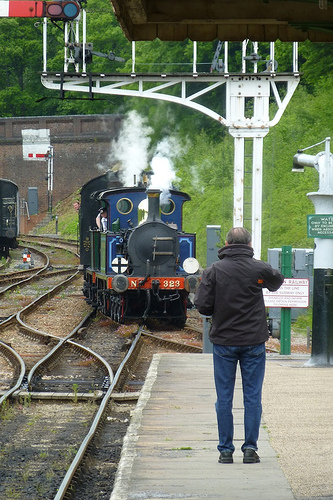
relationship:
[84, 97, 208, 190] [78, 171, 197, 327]
steam on top of train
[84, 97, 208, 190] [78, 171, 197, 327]
steam coming from train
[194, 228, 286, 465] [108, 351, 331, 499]
man on platform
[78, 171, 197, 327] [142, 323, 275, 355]
train on tracks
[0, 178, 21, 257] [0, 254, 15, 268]
train on tracks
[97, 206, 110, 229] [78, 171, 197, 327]
conductor on train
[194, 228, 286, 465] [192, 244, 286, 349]
man wearing a jacket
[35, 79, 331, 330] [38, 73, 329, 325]
hill has grass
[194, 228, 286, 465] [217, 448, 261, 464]
man has on shoes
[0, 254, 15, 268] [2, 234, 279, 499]
tracks are on ground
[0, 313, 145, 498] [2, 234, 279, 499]
tracks are on ground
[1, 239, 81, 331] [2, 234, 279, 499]
tracks are on ground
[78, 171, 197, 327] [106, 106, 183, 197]
train has a smoke stack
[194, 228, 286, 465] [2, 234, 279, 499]
man next to train tracks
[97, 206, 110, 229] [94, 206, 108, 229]
engineer hanging out of window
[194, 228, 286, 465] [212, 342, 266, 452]
man has on blue jeans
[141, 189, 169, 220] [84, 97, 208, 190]
smoke stack has smoke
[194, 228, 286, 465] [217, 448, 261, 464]
man has black shoes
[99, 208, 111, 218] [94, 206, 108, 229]
head hanging out of window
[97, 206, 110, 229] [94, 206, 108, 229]
man hanging out of window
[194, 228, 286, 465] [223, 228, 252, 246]
man has a head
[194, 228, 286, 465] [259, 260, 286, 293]
man has a arm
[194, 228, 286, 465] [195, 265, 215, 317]
man has a arm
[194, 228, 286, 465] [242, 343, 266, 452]
man has a leg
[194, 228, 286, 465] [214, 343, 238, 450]
man has a leg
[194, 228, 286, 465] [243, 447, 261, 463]
man has a feet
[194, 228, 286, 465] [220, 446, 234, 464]
man has a feet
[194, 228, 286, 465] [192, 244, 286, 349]
man wearing a coat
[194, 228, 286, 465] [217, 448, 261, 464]
man wearing shoes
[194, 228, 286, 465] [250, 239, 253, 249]
man has a ear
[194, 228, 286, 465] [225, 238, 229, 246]
man has a ear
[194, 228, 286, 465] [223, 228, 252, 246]
man has hair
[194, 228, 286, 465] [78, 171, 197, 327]
man near train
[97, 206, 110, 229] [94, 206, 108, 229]
man looking out window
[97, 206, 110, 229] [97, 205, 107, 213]
conductor wearing a hat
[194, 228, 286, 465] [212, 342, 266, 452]
man wearing blue jeans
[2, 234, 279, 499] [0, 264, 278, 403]
tracks are in several directions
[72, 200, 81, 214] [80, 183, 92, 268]
man on rear of train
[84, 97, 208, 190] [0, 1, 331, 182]
steam expelling into air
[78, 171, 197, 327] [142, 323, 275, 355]
locomotive traveling down tracks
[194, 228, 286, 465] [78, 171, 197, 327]
man watching locomotive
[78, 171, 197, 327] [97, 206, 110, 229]
train has a conductor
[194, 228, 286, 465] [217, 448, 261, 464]
man has shoes